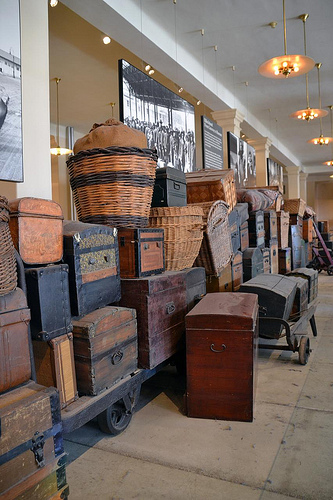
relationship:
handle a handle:
[210, 343, 225, 353] [207, 342, 225, 358]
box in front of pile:
[183, 292, 262, 422] [10, 167, 187, 447]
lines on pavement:
[218, 465, 293, 498] [98, 425, 332, 497]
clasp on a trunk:
[29, 428, 50, 470] [0, 379, 73, 498]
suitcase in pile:
[34, 328, 80, 407] [6, 213, 215, 437]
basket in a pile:
[195, 195, 237, 282] [50, 175, 322, 395]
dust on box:
[204, 297, 227, 312] [184, 291, 260, 423]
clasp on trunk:
[29, 428, 46, 470] [0, 379, 73, 498]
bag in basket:
[73, 118, 147, 156] [66, 141, 158, 228]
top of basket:
[64, 144, 160, 163] [53, 141, 159, 228]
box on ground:
[184, 291, 260, 423] [60, 275, 330, 497]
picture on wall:
[0, 0, 24, 182] [2, 1, 54, 197]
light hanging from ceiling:
[308, 136, 330, 147] [109, 3, 331, 167]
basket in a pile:
[156, 203, 223, 268] [7, 101, 319, 476]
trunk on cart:
[242, 273, 297, 338] [255, 304, 319, 362]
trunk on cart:
[280, 273, 309, 315] [255, 304, 319, 362]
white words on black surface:
[204, 119, 227, 168] [216, 122, 223, 134]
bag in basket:
[67, 119, 157, 149] [65, 145, 158, 230]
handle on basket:
[187, 220, 212, 234] [148, 205, 203, 269]